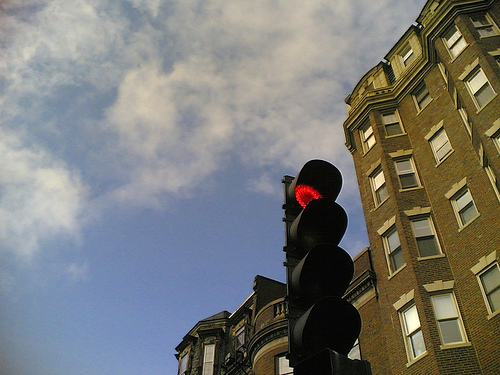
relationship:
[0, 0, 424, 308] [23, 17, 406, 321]
clouds in sky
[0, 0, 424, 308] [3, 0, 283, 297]
clouds in sky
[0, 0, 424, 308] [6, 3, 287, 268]
clouds in sky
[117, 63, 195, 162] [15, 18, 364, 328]
clouds in sky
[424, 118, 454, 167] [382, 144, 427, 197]
window has frame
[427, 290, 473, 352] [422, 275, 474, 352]
window has frame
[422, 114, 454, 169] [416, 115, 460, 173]
window has frame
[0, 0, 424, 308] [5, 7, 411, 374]
clouds in sky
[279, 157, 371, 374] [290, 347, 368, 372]
traffic light on pole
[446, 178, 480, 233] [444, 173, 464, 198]
window in frame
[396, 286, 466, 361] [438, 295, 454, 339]
windows has curtains